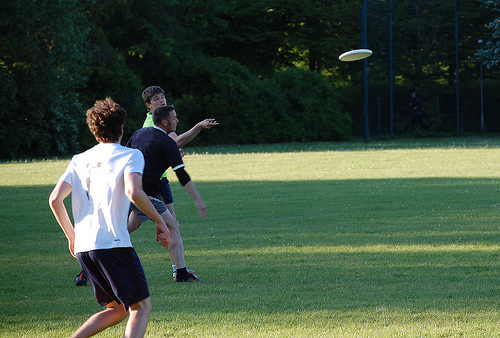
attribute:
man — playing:
[45, 96, 175, 335]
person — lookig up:
[139, 84, 221, 240]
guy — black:
[125, 103, 208, 286]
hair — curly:
[91, 115, 107, 128]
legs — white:
[65, 265, 160, 337]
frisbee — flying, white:
[333, 46, 378, 66]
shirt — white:
[56, 141, 149, 262]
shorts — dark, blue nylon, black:
[70, 248, 161, 315]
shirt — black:
[129, 124, 185, 201]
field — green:
[6, 131, 496, 332]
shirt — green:
[139, 110, 156, 127]